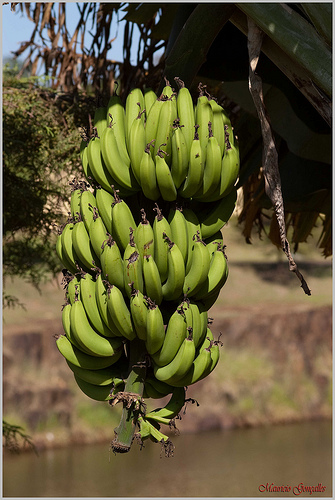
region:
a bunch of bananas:
[43, 83, 258, 452]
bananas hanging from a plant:
[54, 73, 269, 472]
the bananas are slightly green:
[54, 86, 242, 455]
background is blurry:
[10, 330, 333, 495]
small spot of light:
[248, 56, 260, 69]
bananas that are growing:
[44, 51, 266, 458]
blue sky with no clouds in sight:
[1, 2, 173, 89]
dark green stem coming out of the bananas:
[100, 363, 154, 456]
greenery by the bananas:
[2, 61, 79, 288]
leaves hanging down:
[12, 4, 186, 124]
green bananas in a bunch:
[52, 83, 245, 448]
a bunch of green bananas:
[53, 68, 231, 449]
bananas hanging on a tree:
[51, 69, 237, 448]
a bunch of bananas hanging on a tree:
[60, 74, 246, 460]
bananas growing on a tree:
[15, 23, 258, 454]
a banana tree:
[22, 0, 325, 469]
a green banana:
[95, 114, 128, 185]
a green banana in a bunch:
[97, 113, 132, 191]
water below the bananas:
[17, 419, 329, 495]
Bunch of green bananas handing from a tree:
[54, 77, 241, 452]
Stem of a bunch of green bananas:
[110, 342, 148, 453]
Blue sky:
[0, 1, 166, 88]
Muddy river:
[0, 415, 329, 496]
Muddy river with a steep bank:
[1, 299, 327, 488]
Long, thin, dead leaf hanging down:
[244, 18, 308, 294]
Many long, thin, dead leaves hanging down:
[1, 1, 157, 98]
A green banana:
[153, 335, 193, 382]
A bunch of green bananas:
[128, 288, 217, 385]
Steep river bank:
[2, 302, 331, 453]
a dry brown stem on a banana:
[215, 332, 223, 346]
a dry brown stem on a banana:
[185, 324, 192, 335]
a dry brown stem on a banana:
[127, 280, 141, 296]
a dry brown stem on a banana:
[106, 232, 113, 243]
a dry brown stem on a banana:
[71, 182, 80, 187]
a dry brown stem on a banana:
[197, 82, 208, 95]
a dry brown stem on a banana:
[158, 439, 177, 454]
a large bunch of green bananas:
[43, 82, 255, 452]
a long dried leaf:
[247, 40, 312, 300]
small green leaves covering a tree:
[13, 105, 53, 280]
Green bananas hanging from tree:
[48, 72, 250, 451]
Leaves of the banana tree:
[237, 3, 333, 92]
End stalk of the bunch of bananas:
[109, 376, 154, 451]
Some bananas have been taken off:
[133, 409, 179, 454]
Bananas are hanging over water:
[2, 423, 333, 496]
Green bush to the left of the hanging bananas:
[4, 74, 75, 284]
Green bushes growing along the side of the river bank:
[233, 351, 326, 410]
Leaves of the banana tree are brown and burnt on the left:
[10, 2, 150, 79]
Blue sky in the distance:
[4, 5, 163, 68]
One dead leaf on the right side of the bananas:
[241, 29, 310, 298]